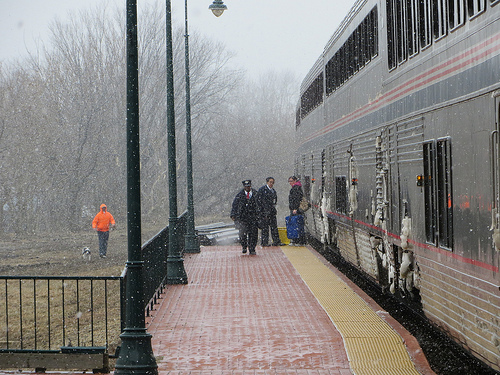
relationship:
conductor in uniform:
[230, 180, 268, 254] [228, 180, 261, 252]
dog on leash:
[81, 244, 91, 262] [86, 229, 95, 246]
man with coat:
[91, 202, 116, 259] [86, 196, 125, 238]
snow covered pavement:
[246, 108, 282, 147] [142, 237, 432, 373]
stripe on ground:
[280, 242, 418, 373] [143, 240, 430, 374]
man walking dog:
[91, 202, 116, 259] [78, 245, 94, 263]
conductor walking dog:
[230, 180, 268, 254] [78, 244, 93, 261]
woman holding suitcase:
[282, 172, 313, 239] [285, 207, 302, 244]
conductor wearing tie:
[230, 180, 268, 254] [245, 187, 250, 200]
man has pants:
[91, 202, 116, 259] [98, 230, 109, 255]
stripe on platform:
[280, 242, 415, 373] [143, 238, 433, 371]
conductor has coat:
[236, 175, 267, 257] [230, 188, 264, 227]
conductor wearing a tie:
[230, 180, 268, 254] [232, 187, 255, 203]